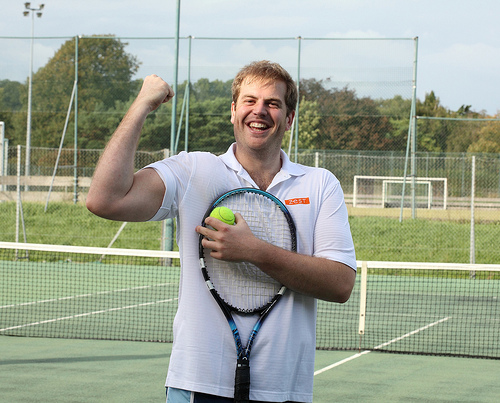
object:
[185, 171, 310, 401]
racket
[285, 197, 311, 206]
logo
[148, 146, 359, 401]
shirt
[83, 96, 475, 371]
field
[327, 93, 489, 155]
forest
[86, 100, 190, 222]
arm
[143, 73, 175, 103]
right hand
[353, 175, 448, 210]
goal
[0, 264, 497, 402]
court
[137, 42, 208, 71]
clouds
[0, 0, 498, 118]
blue sky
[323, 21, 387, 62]
clouds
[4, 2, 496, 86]
sky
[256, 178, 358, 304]
arm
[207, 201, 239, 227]
tennis ball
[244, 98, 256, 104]
eye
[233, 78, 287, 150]
face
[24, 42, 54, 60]
clouds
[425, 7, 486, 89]
sky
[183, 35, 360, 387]
man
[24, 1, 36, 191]
pole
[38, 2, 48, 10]
light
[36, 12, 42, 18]
light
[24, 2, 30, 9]
light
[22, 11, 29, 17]
light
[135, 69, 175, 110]
fist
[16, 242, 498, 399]
tennis court